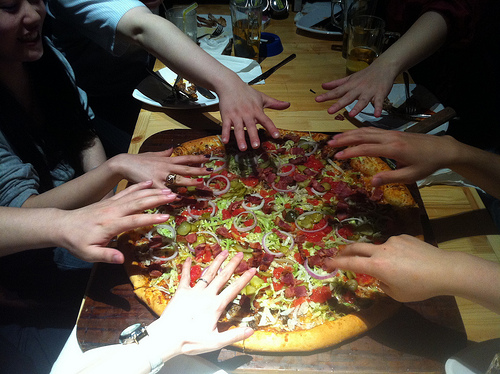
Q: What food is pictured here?
A: Pizza.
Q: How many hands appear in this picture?
A: Seven.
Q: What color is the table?
A: Tan.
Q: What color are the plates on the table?
A: White.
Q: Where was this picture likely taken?
A: A restaurant.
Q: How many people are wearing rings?
A: One.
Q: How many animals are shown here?
A: Zero.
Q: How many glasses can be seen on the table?
A: Three.